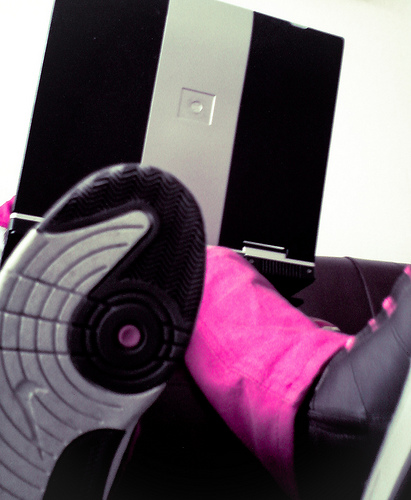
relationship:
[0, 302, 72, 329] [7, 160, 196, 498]
line on shoe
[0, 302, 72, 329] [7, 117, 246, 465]
line on bottom of a shoe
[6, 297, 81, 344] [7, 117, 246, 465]
line on bottom of a shoe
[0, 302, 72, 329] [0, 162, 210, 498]
line on bottom of a bottom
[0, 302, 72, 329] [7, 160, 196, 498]
line on bottom of a shoe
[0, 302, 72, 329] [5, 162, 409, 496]
line on bottom of a shoes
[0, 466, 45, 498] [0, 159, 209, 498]
lines on bottom of a nike shoe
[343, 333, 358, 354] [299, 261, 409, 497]
lace of shoe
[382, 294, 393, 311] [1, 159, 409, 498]
lace of shoe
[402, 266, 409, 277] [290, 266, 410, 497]
lace of shoe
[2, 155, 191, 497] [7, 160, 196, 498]
bottom of shoe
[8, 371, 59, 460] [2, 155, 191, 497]
nike symbol on bottom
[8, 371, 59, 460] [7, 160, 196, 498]
nike symbol on shoe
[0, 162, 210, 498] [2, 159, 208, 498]
bottom of nike shoe